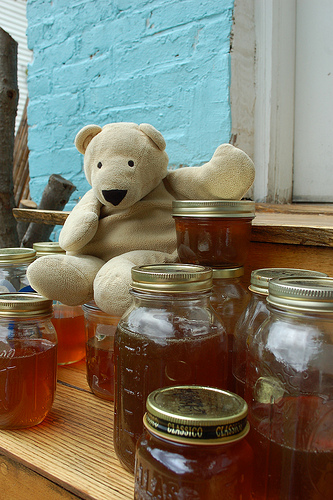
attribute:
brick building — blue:
[34, 10, 225, 119]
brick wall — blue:
[25, 0, 258, 199]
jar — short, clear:
[172, 197, 258, 262]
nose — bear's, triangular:
[100, 186, 131, 206]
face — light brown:
[72, 140, 174, 206]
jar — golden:
[104, 268, 233, 460]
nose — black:
[101, 187, 116, 202]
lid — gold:
[144, 385, 249, 444]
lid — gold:
[171, 199, 255, 216]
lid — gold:
[130, 263, 211, 291]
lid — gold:
[211, 265, 243, 278]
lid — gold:
[0, 292, 52, 319]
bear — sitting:
[73, 120, 167, 222]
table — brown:
[18, 321, 227, 497]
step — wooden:
[218, 178, 330, 246]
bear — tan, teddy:
[28, 112, 256, 312]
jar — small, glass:
[77, 296, 115, 400]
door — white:
[268, 62, 317, 114]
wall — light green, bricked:
[25, 1, 287, 196]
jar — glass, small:
[168, 192, 256, 269]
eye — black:
[93, 151, 110, 178]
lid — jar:
[145, 381, 252, 442]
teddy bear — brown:
[26, 122, 256, 315]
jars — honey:
[0, 200, 319, 491]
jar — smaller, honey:
[173, 198, 255, 268]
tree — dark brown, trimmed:
[0, 24, 65, 244]